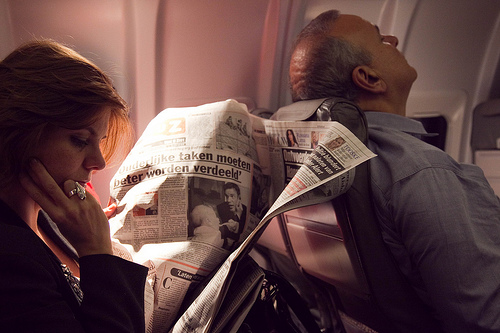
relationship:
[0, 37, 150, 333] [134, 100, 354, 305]
woman reading a newspaper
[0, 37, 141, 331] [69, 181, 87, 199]
woman wearing a ring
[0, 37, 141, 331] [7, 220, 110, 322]
woman wearing jacket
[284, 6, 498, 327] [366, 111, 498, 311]
man in shirt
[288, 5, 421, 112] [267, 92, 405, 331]
head resting on chair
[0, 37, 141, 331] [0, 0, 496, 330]
woman on airplane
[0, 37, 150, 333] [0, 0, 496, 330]
woman on airplane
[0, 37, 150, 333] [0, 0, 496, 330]
woman sitting on airplane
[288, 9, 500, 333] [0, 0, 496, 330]
man on airplane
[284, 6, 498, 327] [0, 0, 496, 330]
man on airplane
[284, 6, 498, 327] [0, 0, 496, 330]
man sleeping on airplane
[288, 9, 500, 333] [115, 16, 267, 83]
man sitting on plane